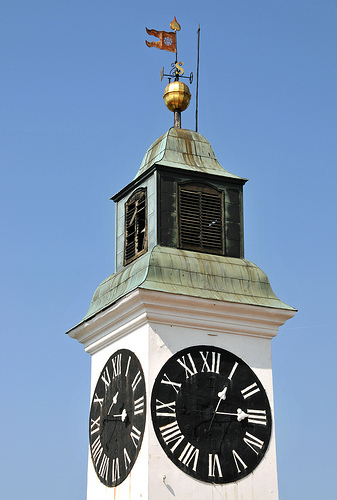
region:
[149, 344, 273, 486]
clock is facing right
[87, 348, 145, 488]
clock is facing left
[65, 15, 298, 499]
tower has two clocks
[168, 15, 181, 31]
weather vane has spade decoration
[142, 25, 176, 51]
weather vane has flag decoration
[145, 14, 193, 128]
weather vane is golden metal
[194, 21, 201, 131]
lightning rod beside weather vane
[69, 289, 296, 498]
tower is painted white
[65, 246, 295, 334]
roof is over clock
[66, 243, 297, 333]
green roof is stained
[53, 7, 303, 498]
clock tower with blue sky in distance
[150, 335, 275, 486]
front clock on tower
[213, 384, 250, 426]
white hands on a clock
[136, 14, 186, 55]
metal flag on top of tower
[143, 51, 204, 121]
weather vane on top of tower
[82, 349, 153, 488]
side clock on a tower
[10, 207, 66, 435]
blue sky in the distance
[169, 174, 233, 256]
shutters on a tower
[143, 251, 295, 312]
shingles on a tower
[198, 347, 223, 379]
roman numeral twelve on a clock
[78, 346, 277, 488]
Clock tower showing two clock faces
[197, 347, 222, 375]
Roman numeral 12 on clock tower face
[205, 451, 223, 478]
Roman numeral 6 on clock tower face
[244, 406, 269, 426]
Roman numeral 3 on clock tower face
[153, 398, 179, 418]
Roman numeral 9 on clock tower face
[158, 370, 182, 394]
Roman numeral 10 on clock tower face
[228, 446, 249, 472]
Roman numeral 5 on clock tower face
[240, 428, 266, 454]
Roman numeral 4 on clock tower face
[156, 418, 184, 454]
Roman numeral 8 on clock tower face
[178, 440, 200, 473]
Roman numeral 7 on clock tower face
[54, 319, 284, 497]
a black and white clock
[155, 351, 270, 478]
a clock with roman numbers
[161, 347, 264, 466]
a clock pointing at 1:15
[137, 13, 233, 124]
the top of a clock house with south being pointed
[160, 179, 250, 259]
an old window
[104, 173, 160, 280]
a broken old window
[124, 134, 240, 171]
some rusting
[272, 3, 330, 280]
a clear blue sky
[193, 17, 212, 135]
a large black lighting rod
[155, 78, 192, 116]
a golden disco ball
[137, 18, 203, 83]
a weather vane on a clock tower.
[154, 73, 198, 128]
a golden orb on a building.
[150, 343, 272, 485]
a large clock on a clock tower.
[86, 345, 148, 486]
a large secondary clock on a clock tower.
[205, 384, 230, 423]
an hour clock hand.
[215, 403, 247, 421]
a minute clock hand.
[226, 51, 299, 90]
a section of clear blue sky.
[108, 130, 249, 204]
a middle section of a clock tower.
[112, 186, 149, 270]
shutters on a clock tower.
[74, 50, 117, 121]
a deep blue sky.